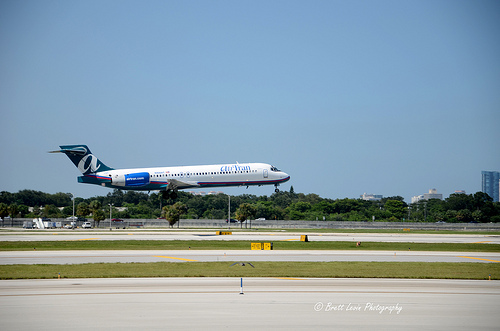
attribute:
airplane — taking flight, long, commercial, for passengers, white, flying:
[46, 117, 292, 221]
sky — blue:
[11, 6, 490, 216]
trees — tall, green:
[0, 191, 499, 223]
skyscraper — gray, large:
[478, 165, 499, 205]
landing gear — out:
[153, 184, 186, 210]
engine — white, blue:
[107, 170, 153, 194]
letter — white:
[74, 149, 101, 180]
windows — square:
[97, 165, 264, 180]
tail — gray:
[41, 132, 106, 192]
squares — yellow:
[247, 237, 279, 265]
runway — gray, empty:
[7, 221, 496, 265]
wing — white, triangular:
[158, 173, 211, 208]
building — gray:
[362, 190, 383, 205]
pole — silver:
[68, 190, 76, 227]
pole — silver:
[105, 200, 120, 237]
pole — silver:
[221, 191, 234, 233]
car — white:
[80, 214, 95, 237]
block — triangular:
[298, 231, 319, 249]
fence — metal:
[0, 209, 233, 231]